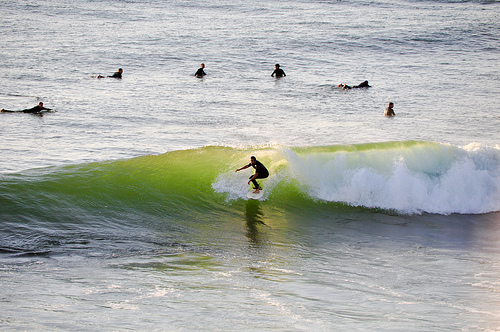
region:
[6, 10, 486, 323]
Photo taken during the day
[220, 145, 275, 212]
One person surfing a wave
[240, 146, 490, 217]
White caps on the wave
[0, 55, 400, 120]
Six surfers waiting for waves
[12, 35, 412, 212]
Seven people wearing wet suits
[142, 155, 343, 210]
Light reflection in the wave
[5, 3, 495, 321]
The weather is warm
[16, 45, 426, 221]
The wet suits are black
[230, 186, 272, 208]
The surfboard is white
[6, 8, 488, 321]
No sharks in the photo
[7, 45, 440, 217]
7 surfers in the water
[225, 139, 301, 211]
this man is shooting the curl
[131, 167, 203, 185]
the wave appears green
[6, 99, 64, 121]
this person is lying on his surfboard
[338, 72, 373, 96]
this person is paddling out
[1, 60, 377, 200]
all these ppl are wearing wet suits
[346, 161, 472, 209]
the wave foam is white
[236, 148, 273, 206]
the man is keeping his balance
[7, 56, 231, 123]
these people are watching the other surfer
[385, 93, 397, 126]
this man is bare chested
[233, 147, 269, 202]
The surfer riding the wave.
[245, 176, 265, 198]
The surfboard the guy on the wave is on.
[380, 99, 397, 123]
The person without a shirt on the right.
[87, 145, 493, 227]
The wave crashing down.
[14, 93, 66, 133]
The surfer lying down on the left.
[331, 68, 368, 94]
The surfer lying down on the right.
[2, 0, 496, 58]
The water in the distance.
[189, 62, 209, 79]
The person in the middle of the group.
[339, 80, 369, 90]
The wet suit the person lying down on the right is wearing.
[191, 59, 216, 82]
surfer in the ocean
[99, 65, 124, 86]
surfer in the ocean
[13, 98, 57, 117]
surfer in the ocean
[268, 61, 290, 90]
surfer in the ocean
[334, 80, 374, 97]
surfer in the ocean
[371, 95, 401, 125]
surfer in the ocean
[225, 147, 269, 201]
surfer in the ocean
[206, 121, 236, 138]
ripple in the ocean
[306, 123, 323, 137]
ripple in the ocean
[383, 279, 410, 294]
ripple in the ocean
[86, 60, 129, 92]
This is a person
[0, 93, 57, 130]
This is a person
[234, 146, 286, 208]
This is a person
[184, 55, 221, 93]
This is a person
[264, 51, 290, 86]
This is a person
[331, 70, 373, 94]
This is a person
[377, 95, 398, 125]
This is a person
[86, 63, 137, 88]
This is a person swimming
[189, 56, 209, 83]
This is a person swimming